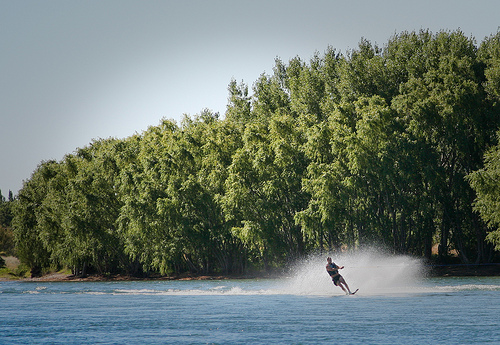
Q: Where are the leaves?
A: On the trees.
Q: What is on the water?
A: White waves.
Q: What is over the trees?
A: Clear skies.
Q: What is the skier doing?
A: Spraying water.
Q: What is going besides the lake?
A: Trees.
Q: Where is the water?
A: In the lake.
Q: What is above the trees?
A: The sky.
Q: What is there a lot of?
A: Trees.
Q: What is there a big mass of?
A: Water.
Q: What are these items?
A: Trees.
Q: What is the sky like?
A: Grey.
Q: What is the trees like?
A: Green.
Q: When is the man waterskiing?
A: Daytime.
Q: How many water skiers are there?
A: One.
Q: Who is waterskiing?
A: The man.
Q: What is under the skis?
A: Water.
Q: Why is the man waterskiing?
A: Recreation.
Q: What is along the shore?
A: Trees.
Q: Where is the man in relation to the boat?
A: Behind.